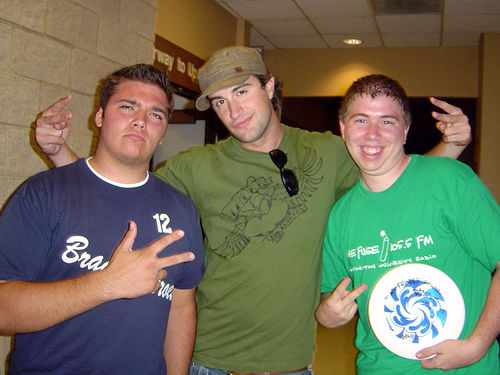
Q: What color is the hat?
A: Green.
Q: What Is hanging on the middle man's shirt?
A: Sunglasses.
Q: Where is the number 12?
A: On the blue shirt.